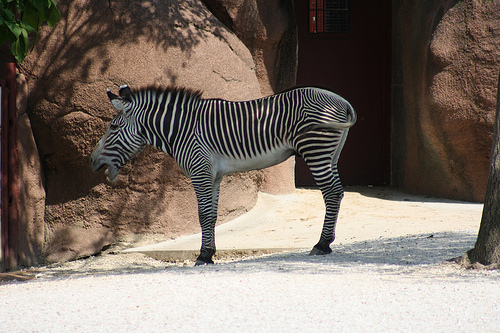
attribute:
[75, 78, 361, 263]
body — curved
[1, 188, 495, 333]
ground — rocky, dirty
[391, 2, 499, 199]
rock — large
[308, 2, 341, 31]
window — small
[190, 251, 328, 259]
hooves — black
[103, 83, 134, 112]
ears — upright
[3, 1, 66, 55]
leaves — green, shadowing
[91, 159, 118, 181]
mouth — open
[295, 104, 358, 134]
tail — swishing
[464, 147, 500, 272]
trunk — brown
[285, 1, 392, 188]
doorway — brown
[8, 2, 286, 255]
wall — rock, cracked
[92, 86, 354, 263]
zebra — looking, braying, standing, striped, big, healthy, adult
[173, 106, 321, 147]
stripes — black, white